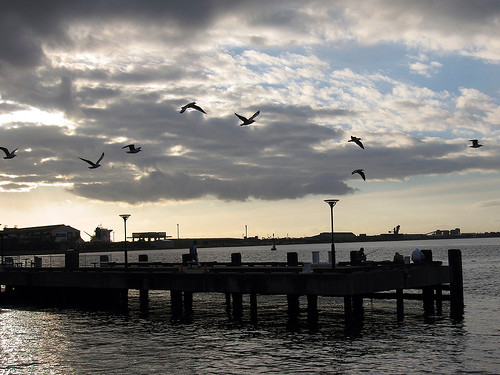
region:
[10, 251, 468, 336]
wooden dock in water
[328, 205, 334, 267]
black metal lamp post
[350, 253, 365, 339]
wooden dock post in water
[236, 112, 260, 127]
bird flying in air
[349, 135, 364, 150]
seagull flying in air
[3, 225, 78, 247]
white building next to water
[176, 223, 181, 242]
wooden electrical pole by water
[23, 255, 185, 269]
metal railing on dock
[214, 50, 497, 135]
white clouds in sky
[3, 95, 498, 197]
grey clouds in sky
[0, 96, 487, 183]
the birds are flying low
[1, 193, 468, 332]
the dock extends out into the water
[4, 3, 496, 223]
the sky is partly cloudy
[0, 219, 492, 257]
buildings line the shoreline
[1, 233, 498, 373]
the water surface is calm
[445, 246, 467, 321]
this is an end post supporting the dock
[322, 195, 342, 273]
one of two visible light polls on the dock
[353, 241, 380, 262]
this man is fishing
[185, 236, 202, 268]
this man is walking on the dock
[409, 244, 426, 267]
this person is likely fishing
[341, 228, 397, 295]
Person fishing on end of pier.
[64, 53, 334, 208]
Large gray clouds in sky.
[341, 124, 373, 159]
Small balck bird in the sky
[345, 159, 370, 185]
Small balck bird in the sky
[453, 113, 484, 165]
Small balck bird in the sky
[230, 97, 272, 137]
Small balck bird in the sky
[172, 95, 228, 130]
Small balck bird in the sky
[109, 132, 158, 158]
Small balck bird in the sky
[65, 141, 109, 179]
Small balck bird in the sky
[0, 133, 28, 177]
Small balck bird in the sky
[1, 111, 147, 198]
Small balck birds in the sky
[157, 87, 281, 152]
Small balck birds in the sky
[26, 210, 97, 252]
Large building in distance.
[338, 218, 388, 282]
Person fishing off of end of pier.